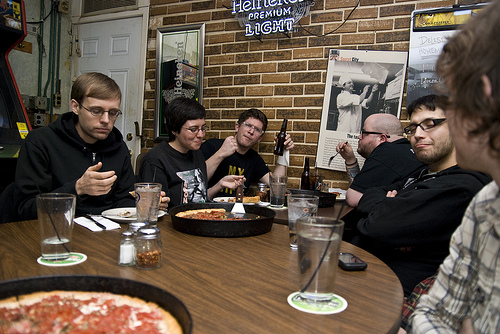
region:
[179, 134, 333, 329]
the table is wooden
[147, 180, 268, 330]
the table is wooden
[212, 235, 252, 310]
the table is wooden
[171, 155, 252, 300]
the table is wooden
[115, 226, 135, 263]
a small salt shaker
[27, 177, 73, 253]
a long black straw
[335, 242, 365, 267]
a small black cellphone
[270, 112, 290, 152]
a tall beer bottle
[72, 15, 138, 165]
part of a white door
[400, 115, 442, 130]
a man's eyeglasses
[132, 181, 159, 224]
a tall clear glass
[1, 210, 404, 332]
a large round table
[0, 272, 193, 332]
part of a pan of pizza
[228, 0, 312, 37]
an alcohol light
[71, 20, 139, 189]
white door in brick wall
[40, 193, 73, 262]
glass of water with black straw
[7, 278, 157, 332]
pizza in black pan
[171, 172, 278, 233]
pizza with spatula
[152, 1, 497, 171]
brown brick wall behind table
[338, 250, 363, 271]
black cell phone on table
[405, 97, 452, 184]
man smirking with black glasses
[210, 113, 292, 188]
man raising beer bottle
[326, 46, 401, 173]
poster of chef on wall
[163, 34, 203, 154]
mirror on brick wall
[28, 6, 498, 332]
men gathered around a table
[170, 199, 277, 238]
partially-eaten pan pizza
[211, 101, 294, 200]
man holding up a bottle of beer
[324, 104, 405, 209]
man with a fork in his hand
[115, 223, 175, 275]
salt and red pepper shakers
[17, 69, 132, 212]
man checking his cell phone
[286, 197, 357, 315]
glass on a coaster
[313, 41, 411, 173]
poster of a man making pizza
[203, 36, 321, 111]
brick wall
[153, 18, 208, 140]
Heineken mirror on the wall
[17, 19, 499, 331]
a group of people sitting around a table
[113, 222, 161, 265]
condiments sitting in glass jars on the table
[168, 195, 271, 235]
a deep dish pizza in the pan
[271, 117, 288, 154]
a bottle of beer in the man's hand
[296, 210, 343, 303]
a glass of water with a straw in it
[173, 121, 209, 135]
the glasses on the woman's face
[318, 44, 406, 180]
a poster on the wall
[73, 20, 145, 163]
a white door in the wall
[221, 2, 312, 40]
a neon beer sign on the wall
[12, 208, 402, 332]
the table the pizzas are sitting on